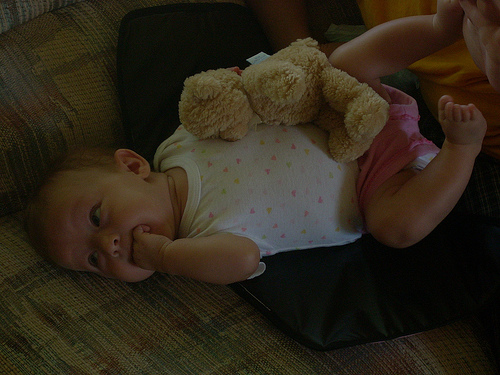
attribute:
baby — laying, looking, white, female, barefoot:
[24, 3, 489, 287]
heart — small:
[263, 167, 271, 177]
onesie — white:
[152, 123, 362, 282]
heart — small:
[234, 157, 243, 166]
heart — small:
[316, 195, 325, 206]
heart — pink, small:
[205, 159, 213, 168]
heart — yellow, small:
[290, 188, 298, 199]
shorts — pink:
[349, 78, 443, 205]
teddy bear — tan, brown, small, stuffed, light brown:
[178, 37, 390, 162]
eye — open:
[88, 200, 108, 229]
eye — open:
[85, 248, 105, 272]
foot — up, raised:
[436, 93, 486, 156]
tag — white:
[246, 50, 272, 65]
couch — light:
[1, 0, 499, 374]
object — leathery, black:
[116, 0, 273, 158]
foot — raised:
[429, 0, 469, 41]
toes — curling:
[437, 93, 481, 123]